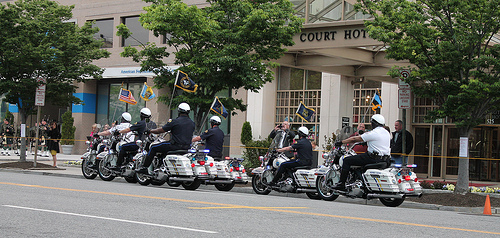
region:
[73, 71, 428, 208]
The police officers driving together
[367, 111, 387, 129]
A helmet of the police officer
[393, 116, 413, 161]
A man by standing by watching the officers drive by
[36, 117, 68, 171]
A woman watching the officers driving buy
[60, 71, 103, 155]
The column on the end of the building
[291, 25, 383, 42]
The black writing on the building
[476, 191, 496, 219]
An orange cone in the middle of the building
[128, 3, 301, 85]
A tree with a lot of green leaves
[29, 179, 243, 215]
A yellow strip in the middle of the street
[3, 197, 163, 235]
the white strip in the middle of the road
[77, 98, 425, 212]
men riding on motocycles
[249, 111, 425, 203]
two white motorcycles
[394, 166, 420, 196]
tail lights of motorcycle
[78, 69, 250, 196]
four motorcyclist holding flags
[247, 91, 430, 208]
two motorcyclist holding flags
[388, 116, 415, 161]
man wearing black coat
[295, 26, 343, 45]
word court on a building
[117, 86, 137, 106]
red white and blue flag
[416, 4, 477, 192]
tree with white sign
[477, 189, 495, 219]
orange street cone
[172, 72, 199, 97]
blue flag with gold trim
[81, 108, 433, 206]
parade of motorcycle policemen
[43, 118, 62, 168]
woman standing on side of road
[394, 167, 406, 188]
emergency vehicle lights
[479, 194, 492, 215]
orange construction cone on road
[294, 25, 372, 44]
Black letters on building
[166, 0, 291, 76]
green leafy tree in front of building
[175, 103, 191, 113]
white police motorcycle helmet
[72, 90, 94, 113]
blue paint on pillar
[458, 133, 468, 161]
white sign posted on tree trunk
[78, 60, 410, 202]
a bunch of cops on parade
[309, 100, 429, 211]
a cop riding a motorcycle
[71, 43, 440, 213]
a bunch of cops riding on motorcycles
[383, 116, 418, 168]
a guy watching the cops ride by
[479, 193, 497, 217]
an orange traffic cone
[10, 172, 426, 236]
a road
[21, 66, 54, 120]
cars will be towed sign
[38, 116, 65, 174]
a woman in a black shirt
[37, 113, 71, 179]
a woman watching the cops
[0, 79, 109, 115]
a blue stripe on a building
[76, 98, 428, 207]
police officers riding motorcycles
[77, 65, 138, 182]
an American flag stand on motorcycle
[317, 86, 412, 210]
an American flag stand on motorcycle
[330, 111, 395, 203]
police officer wears a white shirt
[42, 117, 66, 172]
woman stand near a tree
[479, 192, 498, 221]
an orange cone on side of street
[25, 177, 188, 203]
a yellow line on the road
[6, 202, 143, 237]
a white line on the road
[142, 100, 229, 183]
two police officers wear blue uniforms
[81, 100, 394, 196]
police officers wear white helmets